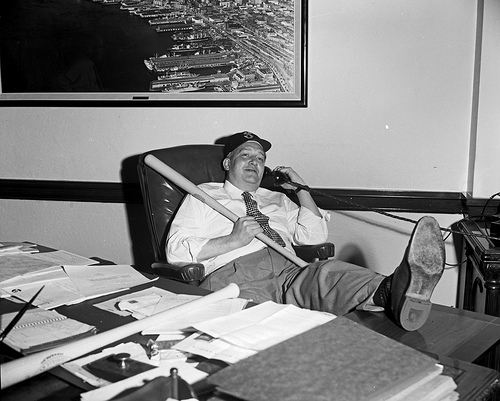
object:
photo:
[1, 0, 308, 101]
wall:
[413, 46, 416, 47]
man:
[166, 131, 446, 330]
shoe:
[397, 216, 446, 333]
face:
[229, 143, 265, 186]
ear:
[223, 158, 230, 171]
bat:
[145, 153, 308, 268]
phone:
[263, 164, 287, 186]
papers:
[48, 262, 103, 288]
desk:
[80, 307, 111, 316]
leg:
[301, 259, 388, 310]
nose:
[249, 159, 258, 166]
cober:
[72, 255, 89, 266]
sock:
[375, 273, 393, 307]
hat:
[225, 130, 272, 156]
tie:
[242, 191, 285, 247]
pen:
[1, 284, 44, 339]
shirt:
[164, 181, 331, 282]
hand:
[231, 216, 264, 244]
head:
[223, 140, 267, 189]